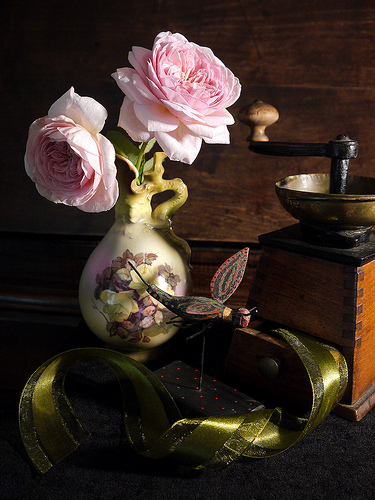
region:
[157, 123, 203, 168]
pink petal on flower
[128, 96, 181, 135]
pink petal on flower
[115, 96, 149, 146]
pink petal on flower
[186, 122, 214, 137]
pink petal on flower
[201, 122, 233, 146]
pink petal on flower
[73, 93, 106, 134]
pink petal on flower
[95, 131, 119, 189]
pink petal on flower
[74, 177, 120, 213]
pink petal on flower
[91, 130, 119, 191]
pink petal on flower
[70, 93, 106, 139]
pink petal on flower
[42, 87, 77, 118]
pink petal on flower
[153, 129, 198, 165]
pink petal on flower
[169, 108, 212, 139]
pink petal on flower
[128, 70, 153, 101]
pink petal on flower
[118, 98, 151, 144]
light pink flower petal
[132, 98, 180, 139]
light pink flower petal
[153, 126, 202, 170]
light pink flower petal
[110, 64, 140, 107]
light pink flower petal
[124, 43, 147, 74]
light pink flower petal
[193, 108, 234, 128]
light pink flower petal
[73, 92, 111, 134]
light pink flower petal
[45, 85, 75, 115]
light pink flower petal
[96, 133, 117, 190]
light pink flower petal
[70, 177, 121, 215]
light pink flower petal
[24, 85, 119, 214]
Pink flower of plant in vase.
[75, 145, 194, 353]
Vase holding pink flowers.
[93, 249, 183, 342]
Flower pattern on vase.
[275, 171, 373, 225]
Bowl with lever on it.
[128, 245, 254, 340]
Dragonfly decoration on stick.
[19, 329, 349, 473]
Golden swirly cloth decoration.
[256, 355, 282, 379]
knob of the drawer.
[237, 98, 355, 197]
crank attached to the bowl.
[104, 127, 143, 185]
Leaf of plant in vase.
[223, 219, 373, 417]
Small drawer with bowl on top.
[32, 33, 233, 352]
flowers in a floral design vase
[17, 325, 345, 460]
a strip of gold ribbon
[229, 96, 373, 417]
a metal and wooden grinding mill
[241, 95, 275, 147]
a wooden handle on a grinding mill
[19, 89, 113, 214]
the pink petals of a flower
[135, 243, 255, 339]
a artwork creation of a bug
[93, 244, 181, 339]
flowers painted on a vase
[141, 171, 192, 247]
a handle on a vase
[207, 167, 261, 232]
the grain of a piece of wood